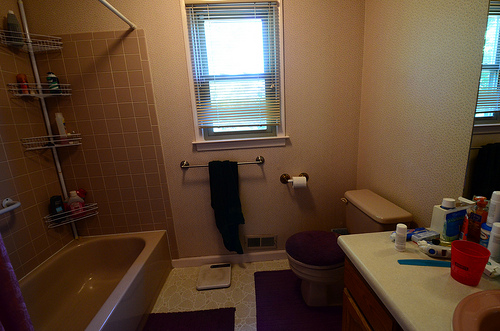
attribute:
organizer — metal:
[3, 6, 105, 238]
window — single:
[190, 11, 289, 141]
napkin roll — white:
[275, 170, 305, 200]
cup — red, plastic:
[441, 231, 491, 287]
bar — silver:
[159, 142, 275, 178]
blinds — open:
[190, 5, 280, 136]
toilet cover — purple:
[285, 231, 345, 268]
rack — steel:
[1, 0, 101, 241]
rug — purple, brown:
[248, 267, 343, 327]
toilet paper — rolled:
[287, 174, 314, 190]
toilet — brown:
[285, 184, 414, 316]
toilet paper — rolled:
[290, 174, 307, 189]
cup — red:
[448, 237, 496, 289]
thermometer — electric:
[379, 210, 474, 298]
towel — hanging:
[203, 157, 251, 261]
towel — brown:
[209, 161, 246, 252]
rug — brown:
[131, 303, 237, 329]